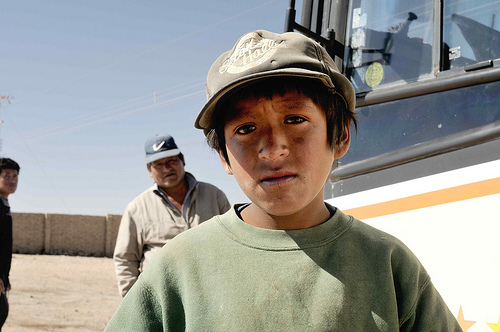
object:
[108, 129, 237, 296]
man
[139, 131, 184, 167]
hat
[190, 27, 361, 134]
cap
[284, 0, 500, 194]
bus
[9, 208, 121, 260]
fence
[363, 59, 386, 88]
sticker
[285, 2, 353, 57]
mirror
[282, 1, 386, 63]
side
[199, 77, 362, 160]
hair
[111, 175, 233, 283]
shirt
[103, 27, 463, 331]
boy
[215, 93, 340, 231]
smiling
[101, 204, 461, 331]
sweater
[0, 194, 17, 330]
clothing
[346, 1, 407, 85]
windshield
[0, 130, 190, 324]
people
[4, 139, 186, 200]
reluctant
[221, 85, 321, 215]
ndicisive look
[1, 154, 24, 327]
man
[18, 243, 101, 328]
area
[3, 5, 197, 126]
sky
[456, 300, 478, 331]
star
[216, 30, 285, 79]
design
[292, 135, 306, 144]
mark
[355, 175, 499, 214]
line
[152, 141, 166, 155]
nike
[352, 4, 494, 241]
bus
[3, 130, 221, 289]
male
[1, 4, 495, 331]
camera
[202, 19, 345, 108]
hat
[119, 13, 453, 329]
boy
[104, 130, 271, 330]
man